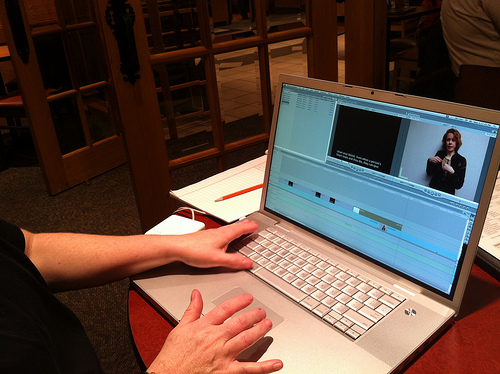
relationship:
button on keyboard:
[350, 297, 363, 315] [175, 127, 460, 371]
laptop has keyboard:
[131, 72, 498, 372] [238, 220, 410, 332]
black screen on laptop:
[323, 104, 408, 175] [131, 72, 498, 372]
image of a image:
[424, 123, 474, 195] [426, 127, 466, 195]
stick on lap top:
[393, 305, 428, 318] [139, 69, 487, 350]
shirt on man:
[437, 0, 499, 76] [437, 0, 499, 108]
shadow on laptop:
[457, 270, 497, 311] [131, 72, 498, 372]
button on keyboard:
[380, 292, 400, 306] [232, 218, 409, 340]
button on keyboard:
[389, 290, 409, 302] [215, 208, 410, 343]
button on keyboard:
[330, 301, 351, 314] [231, 227, 406, 339]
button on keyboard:
[344, 302, 374, 329] [245, 204, 415, 350]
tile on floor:
[285, 56, 312, 71] [211, 33, 285, 112]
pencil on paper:
[214, 181, 263, 203] [167, 147, 267, 222]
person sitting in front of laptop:
[0, 200, 282, 372] [131, 72, 498, 372]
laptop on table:
[129, 72, 498, 374] [398, 263, 498, 372]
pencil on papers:
[214, 181, 263, 203] [166, 153, 269, 223]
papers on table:
[159, 154, 340, 249] [127, 166, 498, 371]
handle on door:
[103, 0, 145, 100] [100, 4, 157, 99]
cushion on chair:
[0, 82, 62, 111] [0, 82, 63, 116]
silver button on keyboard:
[374, 282, 392, 295] [190, 215, 409, 354]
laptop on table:
[131, 72, 498, 372] [128, 201, 499, 371]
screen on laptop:
[268, 80, 493, 296] [129, 72, 498, 374]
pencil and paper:
[214, 181, 263, 203] [191, 185, 221, 202]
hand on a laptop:
[146, 285, 286, 372] [131, 72, 498, 372]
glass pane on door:
[49, 97, 89, 156] [8, 0, 125, 190]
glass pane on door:
[32, 32, 72, 97] [8, 0, 125, 190]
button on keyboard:
[348, 308, 374, 327] [218, 227, 408, 345]